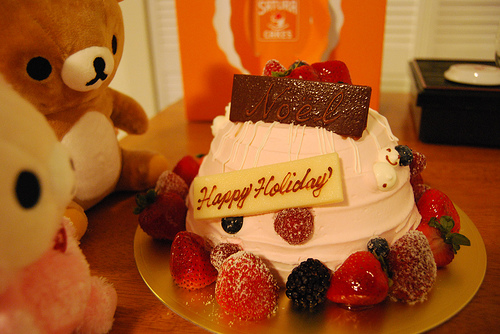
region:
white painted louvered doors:
[143, 2, 498, 113]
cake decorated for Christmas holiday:
[131, 58, 473, 319]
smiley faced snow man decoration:
[369, 144, 402, 192]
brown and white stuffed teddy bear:
[1, 0, 171, 243]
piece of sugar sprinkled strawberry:
[213, 249, 280, 322]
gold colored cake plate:
[131, 200, 491, 332]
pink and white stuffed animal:
[1, 74, 121, 332]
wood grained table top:
[76, 88, 498, 332]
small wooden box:
[406, 53, 499, 150]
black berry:
[284, 256, 335, 313]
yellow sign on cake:
[196, 145, 336, 211]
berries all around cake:
[142, 138, 462, 313]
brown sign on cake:
[238, 72, 395, 166]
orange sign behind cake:
[174, 0, 405, 102]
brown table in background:
[401, 47, 499, 164]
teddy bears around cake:
[12, 5, 151, 327]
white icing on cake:
[211, 119, 382, 254]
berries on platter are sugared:
[169, 185, 449, 304]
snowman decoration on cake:
[370, 142, 406, 219]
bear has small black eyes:
[19, 47, 48, 74]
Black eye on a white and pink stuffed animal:
[11, 167, 41, 210]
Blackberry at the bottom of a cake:
[288, 259, 326, 304]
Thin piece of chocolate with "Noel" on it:
[236, 75, 355, 125]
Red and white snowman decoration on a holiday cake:
[383, 145, 403, 165]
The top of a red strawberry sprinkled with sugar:
[226, 251, 261, 275]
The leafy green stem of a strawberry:
[439, 219, 454, 236]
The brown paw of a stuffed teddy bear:
[128, 105, 146, 133]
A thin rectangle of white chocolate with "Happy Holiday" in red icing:
[197, 168, 338, 208]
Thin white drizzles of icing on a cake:
[322, 138, 339, 152]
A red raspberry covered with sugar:
[277, 215, 309, 237]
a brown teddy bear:
[1, 1, 163, 240]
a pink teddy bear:
[2, 79, 115, 332]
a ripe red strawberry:
[171, 229, 217, 289]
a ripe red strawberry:
[417, 186, 464, 235]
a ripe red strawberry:
[419, 217, 469, 267]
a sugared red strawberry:
[389, 225, 439, 303]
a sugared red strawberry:
[214, 247, 281, 322]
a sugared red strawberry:
[210, 240, 240, 271]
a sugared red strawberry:
[277, 207, 312, 241]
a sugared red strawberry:
[154, 169, 188, 197]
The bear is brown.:
[5, 6, 168, 204]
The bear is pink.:
[5, 98, 123, 330]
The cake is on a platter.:
[163, 52, 475, 322]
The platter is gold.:
[123, 153, 463, 332]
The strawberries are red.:
[142, 151, 475, 315]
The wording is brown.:
[185, 155, 352, 222]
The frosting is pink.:
[206, 110, 434, 280]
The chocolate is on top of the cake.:
[222, 70, 374, 140]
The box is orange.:
[173, 4, 385, 124]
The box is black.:
[405, 53, 498, 143]